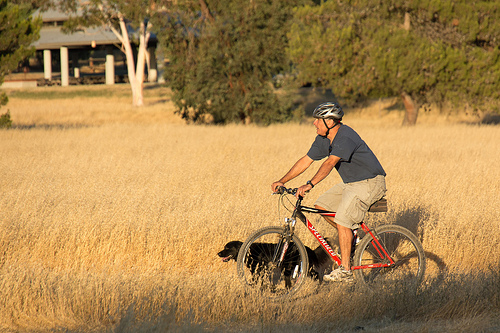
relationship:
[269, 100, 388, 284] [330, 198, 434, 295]
man has shadow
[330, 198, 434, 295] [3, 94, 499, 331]
shadow in grass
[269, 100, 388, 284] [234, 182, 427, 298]
man riding bike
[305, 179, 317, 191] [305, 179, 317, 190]
watch worn on wrist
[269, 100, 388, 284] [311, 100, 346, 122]
man wearing helmet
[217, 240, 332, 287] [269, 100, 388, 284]
dog beside man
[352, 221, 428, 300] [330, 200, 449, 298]
wheel has shadow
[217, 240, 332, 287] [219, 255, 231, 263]
dog has tongue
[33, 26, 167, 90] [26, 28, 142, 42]
pavilion has roof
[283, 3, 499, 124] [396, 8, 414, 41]
tree has branch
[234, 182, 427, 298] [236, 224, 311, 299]
bike has front tire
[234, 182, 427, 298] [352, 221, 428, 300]
bike has rear tire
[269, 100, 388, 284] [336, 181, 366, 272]
man has left leg